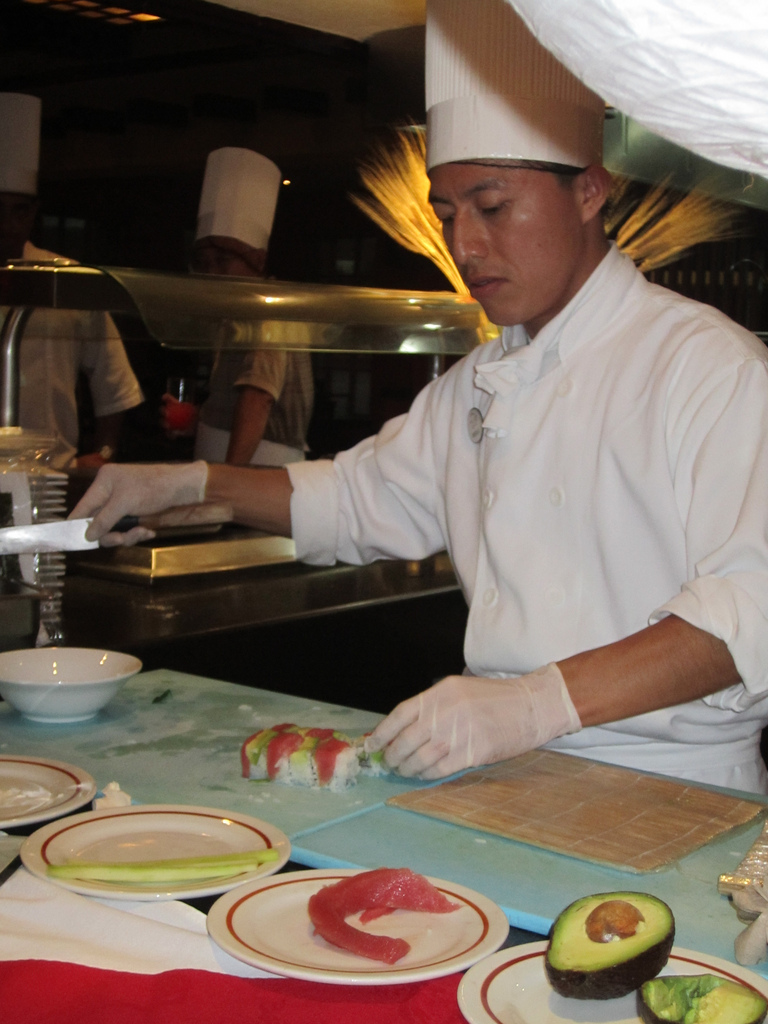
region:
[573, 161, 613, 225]
Ear of a man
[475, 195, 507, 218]
Eye of a man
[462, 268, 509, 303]
Mouth of a man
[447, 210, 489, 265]
Nose of a man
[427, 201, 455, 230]
Eye of a man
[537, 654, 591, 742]
Wrist of a man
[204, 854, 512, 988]
Raw food on a plate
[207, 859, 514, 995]
Raw food on a white plate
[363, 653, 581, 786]
Glove on a hand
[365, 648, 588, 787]
White glove on a hand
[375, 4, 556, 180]
chef has white hat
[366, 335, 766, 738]
chef has white shirt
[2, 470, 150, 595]
chef is holding knife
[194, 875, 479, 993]
pink fish on plate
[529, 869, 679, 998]
halved avocado on plate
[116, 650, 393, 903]
cutting board is blue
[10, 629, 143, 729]
white bowl on board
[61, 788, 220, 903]
white and brown plate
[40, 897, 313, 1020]
red and white cloth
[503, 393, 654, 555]
The man is in white.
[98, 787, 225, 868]
The plate is white.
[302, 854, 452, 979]
The food is not cooked.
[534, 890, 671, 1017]
The food is ready.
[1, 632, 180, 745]
The bowl is empty.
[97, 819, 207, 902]
The celery is being prepared.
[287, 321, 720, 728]
chef has white apron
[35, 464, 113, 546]
chef holds steel knife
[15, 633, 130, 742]
white bowl under knife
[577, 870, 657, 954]
brown pit in avocado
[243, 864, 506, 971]
white and brown plate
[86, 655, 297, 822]
cutting board is blue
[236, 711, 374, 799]
Sushi being created on counter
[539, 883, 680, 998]
Opened avocado on the plate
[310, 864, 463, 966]
Plate of sliced meat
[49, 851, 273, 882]
Sliced cucumber on the plate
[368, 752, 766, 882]
Rolling mat for sushi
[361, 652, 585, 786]
Glove over the hand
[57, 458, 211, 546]
Glove over the hand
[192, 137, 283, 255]
Tall hat on the chef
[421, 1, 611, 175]
Tall hat on the chef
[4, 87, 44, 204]
Tall hat on the chef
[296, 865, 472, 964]
A piece of food.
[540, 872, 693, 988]
A piece of food.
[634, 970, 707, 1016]
A piece of food.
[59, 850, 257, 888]
A piece of food.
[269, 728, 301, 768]
A piece of food.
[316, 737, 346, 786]
A piece of food.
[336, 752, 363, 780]
A piece of food.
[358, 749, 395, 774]
A piece of food.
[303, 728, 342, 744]
A piece of food.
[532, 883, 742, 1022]
Avocado on white plate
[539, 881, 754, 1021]
Vegetable on white plate